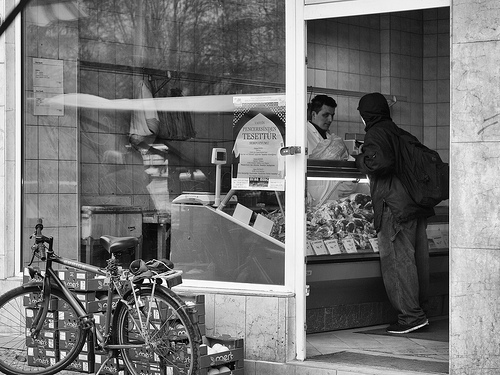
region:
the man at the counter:
[346, 89, 451, 338]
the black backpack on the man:
[391, 128, 451, 211]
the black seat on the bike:
[96, 231, 139, 258]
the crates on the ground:
[193, 335, 245, 373]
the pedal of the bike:
[76, 311, 103, 351]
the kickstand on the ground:
[91, 350, 117, 374]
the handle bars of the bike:
[30, 211, 50, 259]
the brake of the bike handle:
[23, 246, 39, 266]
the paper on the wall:
[29, 53, 67, 121]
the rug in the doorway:
[303, 341, 450, 374]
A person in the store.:
[349, 95, 433, 340]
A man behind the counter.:
[303, 92, 358, 152]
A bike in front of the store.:
[14, 238, 198, 365]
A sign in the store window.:
[218, 78, 315, 202]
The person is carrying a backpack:
[386, 112, 451, 201]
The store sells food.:
[191, 19, 428, 334]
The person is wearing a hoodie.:
[345, 83, 403, 184]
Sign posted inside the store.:
[18, 55, 84, 142]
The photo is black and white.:
[32, 13, 465, 371]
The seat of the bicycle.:
[89, 221, 149, 266]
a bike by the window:
[4, 217, 206, 374]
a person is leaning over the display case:
[351, 90, 451, 336]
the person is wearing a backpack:
[387, 125, 453, 217]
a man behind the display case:
[303, 91, 358, 166]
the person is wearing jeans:
[371, 202, 436, 324]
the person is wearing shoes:
[381, 308, 433, 338]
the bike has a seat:
[94, 230, 139, 254]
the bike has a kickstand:
[86, 351, 113, 373]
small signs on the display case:
[302, 234, 383, 259]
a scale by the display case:
[169, 140, 245, 212]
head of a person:
[354, 88, 396, 128]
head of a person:
[311, 94, 338, 129]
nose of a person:
[326, 113, 334, 122]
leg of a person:
[373, 293, 435, 345]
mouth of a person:
[317, 120, 332, 130]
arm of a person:
[337, 129, 399, 186]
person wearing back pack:
[342, 85, 453, 354]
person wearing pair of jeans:
[332, 81, 477, 348]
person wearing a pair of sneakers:
[341, 83, 457, 358]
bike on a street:
[20, 232, 219, 372]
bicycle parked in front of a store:
[1, 208, 198, 373]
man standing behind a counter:
[303, 89, 353, 164]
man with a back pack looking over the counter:
[348, 88, 448, 343]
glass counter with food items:
[303, 164, 386, 254]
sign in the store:
[222, 99, 290, 195]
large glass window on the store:
[21, 0, 291, 290]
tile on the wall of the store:
[298, 11, 447, 152]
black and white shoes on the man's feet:
[388, 315, 432, 334]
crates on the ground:
[26, 268, 240, 370]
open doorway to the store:
[305, 14, 453, 369]